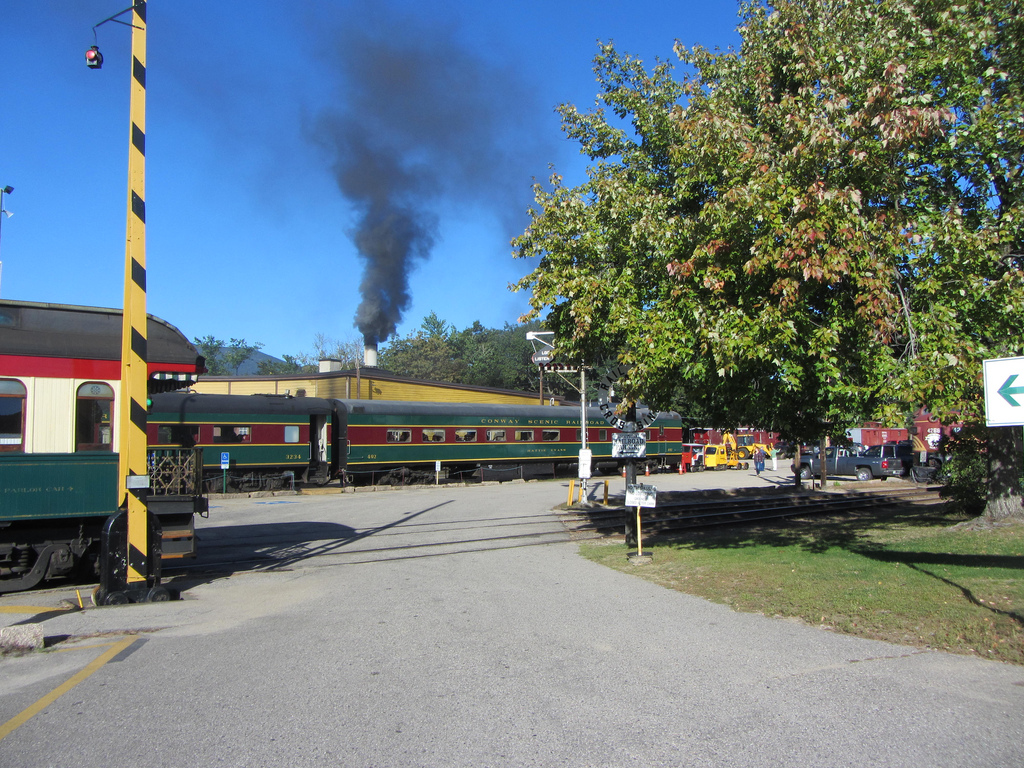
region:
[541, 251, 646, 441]
A person eating a orange.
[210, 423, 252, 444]
the rectangle window of the train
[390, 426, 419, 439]
the rectangle window of the train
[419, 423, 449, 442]
the rectangle window of the train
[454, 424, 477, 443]
the rectangle window of the train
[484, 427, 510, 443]
the rectangle window of the train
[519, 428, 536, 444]
the rectangle window of the train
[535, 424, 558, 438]
the rectangle window of the train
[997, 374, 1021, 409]
the green arrow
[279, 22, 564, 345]
the dark grey smoke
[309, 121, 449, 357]
Black smoke in sky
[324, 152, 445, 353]
Black smoke in the air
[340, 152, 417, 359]
Smoke coming out of smoke stack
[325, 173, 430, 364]
Black smoke coming out of smoke stack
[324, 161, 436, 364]
Smoke coming out of building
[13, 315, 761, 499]
Green train near the building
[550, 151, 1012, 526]
Tree near the train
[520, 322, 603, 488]
Pole near the train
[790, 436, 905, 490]
Silver truck near the train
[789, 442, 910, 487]
Silver truck parked near train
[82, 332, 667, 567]
Passenger train in front of the factory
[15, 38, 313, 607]
Yellow and black rail at the railroad crossing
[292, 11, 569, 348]
cloud of black smoke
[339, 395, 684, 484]
green and red train card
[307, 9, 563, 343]
The black smog in the air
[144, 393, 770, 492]
The train is green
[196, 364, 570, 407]
The yellow house behind the train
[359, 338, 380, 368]
The white chimney behind the train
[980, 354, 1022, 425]
The white sign in the grass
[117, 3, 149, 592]
The beam in the air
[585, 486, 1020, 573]
The shadow on the grass field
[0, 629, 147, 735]
The yellow paint on the ground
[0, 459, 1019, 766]
The cement road beside the train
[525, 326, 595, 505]
The streetlight over the road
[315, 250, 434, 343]
smoke from the train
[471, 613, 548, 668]
the ground is asphalt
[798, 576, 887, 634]
the grass is dry